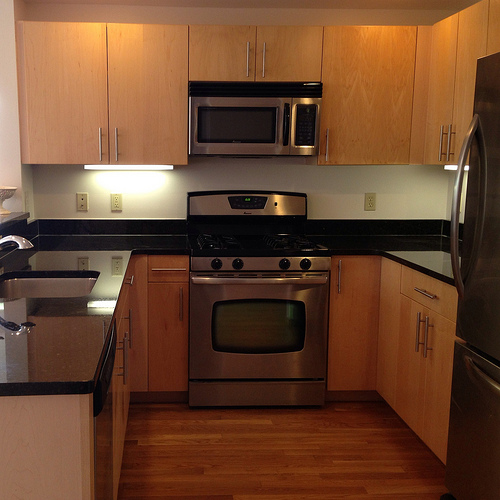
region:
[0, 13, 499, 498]
A nice modern kitchen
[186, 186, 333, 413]
Stainless steal stove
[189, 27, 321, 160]
Stainless steel microwave mounted under cabinets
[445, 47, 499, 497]
Stainless still freezer and refrigerator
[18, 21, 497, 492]
Blonde wood cabinets with steel hardware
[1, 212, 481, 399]
Nice counter tops likely granite or Formica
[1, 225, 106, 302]
Single sink and faucett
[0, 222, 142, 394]
Counter top so clean you can see reflections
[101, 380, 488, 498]
Hardwood or laminate floors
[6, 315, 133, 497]
Stainless steel dishwasher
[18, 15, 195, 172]
wood kitchen cabinet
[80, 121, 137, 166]
metal kitchen cabinet handles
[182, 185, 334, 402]
stainless steel oven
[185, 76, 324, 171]
stainless steel microwave oven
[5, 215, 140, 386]
black high gloss kitchen counter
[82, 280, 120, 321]
reflection on kitchen counter top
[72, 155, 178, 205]
under cabinet kitchen light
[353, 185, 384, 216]
electrical outlet with two sockets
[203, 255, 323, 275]
black oven control knobs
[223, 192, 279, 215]
electronic oven information display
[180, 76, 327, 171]
Microwave is silver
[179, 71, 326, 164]
Microwave is turn off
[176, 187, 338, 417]
Stove is in middle of kitchen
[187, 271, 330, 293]
Handle of oven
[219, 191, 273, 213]
Display of time in top of stove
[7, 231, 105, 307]
Sink on left side of kitchen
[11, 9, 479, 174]
Counters are made of wood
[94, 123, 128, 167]
Handles of counter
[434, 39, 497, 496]
Refrigerator is brown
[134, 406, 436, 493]
Floor is brown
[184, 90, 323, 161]
The microwave above the oven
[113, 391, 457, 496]
The wood floors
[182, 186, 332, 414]
The black and silver stove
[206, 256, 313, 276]
The black knobs on the stove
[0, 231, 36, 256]
the faucet above the sink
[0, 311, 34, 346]
The reflection of the faucet on the counter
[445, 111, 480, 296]
The handle to the fridge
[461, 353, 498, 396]
The handle to the freezer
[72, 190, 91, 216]
The telephone outlet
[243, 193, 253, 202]
The green writing on the stoves clock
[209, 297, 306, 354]
window on oven door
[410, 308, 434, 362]
pair of vertical metal cabinet handles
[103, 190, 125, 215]
electrical wall outlet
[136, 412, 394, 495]
wooden kitchen floor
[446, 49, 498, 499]
refrigerator with attached freezer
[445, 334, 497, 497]
shiny freezer located beneath refrigerator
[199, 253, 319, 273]
black stove control knobs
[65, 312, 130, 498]
built in under the counter dishwasher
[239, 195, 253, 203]
oven clock display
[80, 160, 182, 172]
fluorescent under the counter lighting